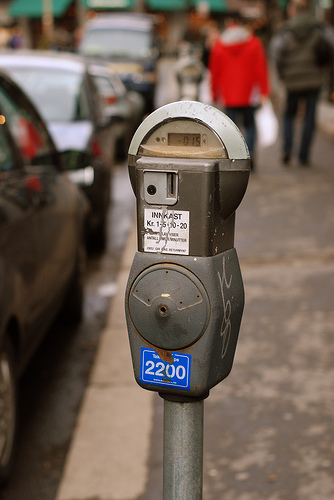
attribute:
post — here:
[149, 371, 225, 498]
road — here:
[42, 236, 93, 454]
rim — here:
[1, 362, 35, 475]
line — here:
[176, 287, 205, 313]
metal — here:
[152, 402, 242, 454]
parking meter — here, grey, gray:
[68, 57, 294, 455]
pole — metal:
[141, 382, 237, 495]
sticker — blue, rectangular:
[123, 340, 208, 416]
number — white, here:
[138, 355, 193, 377]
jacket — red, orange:
[202, 26, 278, 110]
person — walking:
[207, 12, 290, 177]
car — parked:
[0, 67, 103, 234]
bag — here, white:
[256, 94, 284, 155]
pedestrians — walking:
[178, 24, 332, 159]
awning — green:
[13, 6, 76, 17]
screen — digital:
[155, 125, 227, 158]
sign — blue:
[118, 338, 219, 399]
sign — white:
[138, 209, 200, 265]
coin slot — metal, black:
[158, 177, 187, 199]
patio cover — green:
[121, 0, 213, 18]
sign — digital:
[148, 107, 233, 165]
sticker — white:
[125, 207, 231, 280]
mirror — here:
[53, 143, 98, 194]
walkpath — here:
[259, 144, 331, 499]